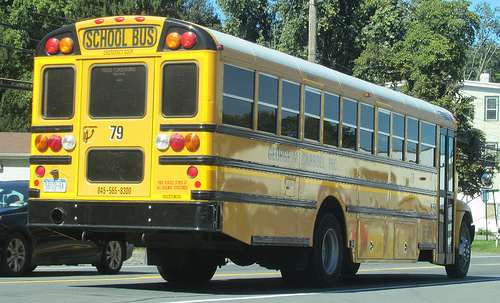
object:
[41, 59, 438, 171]
windows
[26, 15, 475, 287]
bus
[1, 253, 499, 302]
lot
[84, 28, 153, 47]
words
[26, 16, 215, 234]
back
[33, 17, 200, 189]
lights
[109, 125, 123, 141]
number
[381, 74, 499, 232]
building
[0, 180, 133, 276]
car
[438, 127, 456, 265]
door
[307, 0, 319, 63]
pole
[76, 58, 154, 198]
exit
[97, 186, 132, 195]
number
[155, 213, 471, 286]
wheels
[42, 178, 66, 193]
plate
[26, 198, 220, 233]
bumper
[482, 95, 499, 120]
window